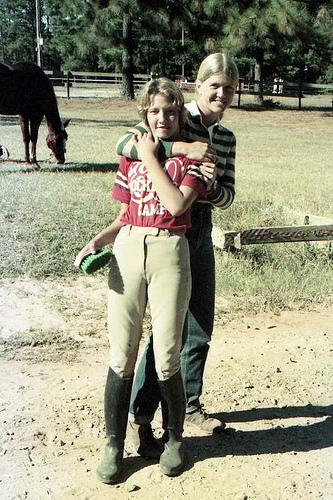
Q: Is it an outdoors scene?
A: Yes, it is outdoors.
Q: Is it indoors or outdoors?
A: It is outdoors.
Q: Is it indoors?
A: No, it is outdoors.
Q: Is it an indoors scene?
A: No, it is outdoors.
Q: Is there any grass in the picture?
A: Yes, there is grass.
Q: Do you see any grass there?
A: Yes, there is grass.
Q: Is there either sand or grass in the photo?
A: Yes, there is grass.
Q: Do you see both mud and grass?
A: No, there is grass but no mud.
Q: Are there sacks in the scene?
A: No, there are no sacks.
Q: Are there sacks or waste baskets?
A: No, there are no sacks or waste baskets.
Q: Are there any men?
A: No, there are no men.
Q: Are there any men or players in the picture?
A: No, there are no men or players.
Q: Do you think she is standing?
A: Yes, the girl is standing.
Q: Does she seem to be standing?
A: Yes, the girl is standing.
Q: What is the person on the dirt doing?
A: The girl is standing.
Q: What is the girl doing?
A: The girl is standing.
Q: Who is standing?
A: The girl is standing.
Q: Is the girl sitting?
A: No, the girl is standing.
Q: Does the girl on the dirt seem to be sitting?
A: No, the girl is standing.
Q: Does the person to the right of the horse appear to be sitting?
A: No, the girl is standing.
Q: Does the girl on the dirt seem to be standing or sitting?
A: The girl is standing.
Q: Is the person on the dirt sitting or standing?
A: The girl is standing.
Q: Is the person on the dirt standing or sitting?
A: The girl is standing.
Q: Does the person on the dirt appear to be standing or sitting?
A: The girl is standing.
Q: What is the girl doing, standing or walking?
A: The girl is standing.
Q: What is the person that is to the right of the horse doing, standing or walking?
A: The girl is standing.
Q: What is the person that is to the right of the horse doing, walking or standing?
A: The girl is standing.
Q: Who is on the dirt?
A: The girl is on the dirt.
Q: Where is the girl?
A: The girl is on the dirt.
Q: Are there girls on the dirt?
A: Yes, there is a girl on the dirt.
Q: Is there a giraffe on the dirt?
A: No, there is a girl on the dirt.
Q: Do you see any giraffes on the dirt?
A: No, there is a girl on the dirt.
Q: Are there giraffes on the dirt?
A: No, there is a girl on the dirt.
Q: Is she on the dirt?
A: Yes, the girl is on the dirt.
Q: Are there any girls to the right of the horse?
A: Yes, there is a girl to the right of the horse.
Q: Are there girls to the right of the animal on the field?
A: Yes, there is a girl to the right of the horse.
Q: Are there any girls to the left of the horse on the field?
A: No, the girl is to the right of the horse.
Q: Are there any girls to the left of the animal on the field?
A: No, the girl is to the right of the horse.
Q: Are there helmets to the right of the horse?
A: No, there is a girl to the right of the horse.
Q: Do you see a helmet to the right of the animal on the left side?
A: No, there is a girl to the right of the horse.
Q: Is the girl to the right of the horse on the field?
A: Yes, the girl is to the right of the horse.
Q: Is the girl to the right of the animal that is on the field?
A: Yes, the girl is to the right of the horse.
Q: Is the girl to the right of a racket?
A: No, the girl is to the right of the horse.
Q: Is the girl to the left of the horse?
A: No, the girl is to the right of the horse.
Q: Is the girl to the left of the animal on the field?
A: No, the girl is to the right of the horse.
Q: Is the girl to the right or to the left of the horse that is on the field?
A: The girl is to the right of the horse.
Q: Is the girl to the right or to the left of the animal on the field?
A: The girl is to the right of the horse.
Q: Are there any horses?
A: Yes, there is a horse.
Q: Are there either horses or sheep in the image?
A: Yes, there is a horse.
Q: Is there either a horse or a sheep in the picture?
A: Yes, there is a horse.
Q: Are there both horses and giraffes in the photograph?
A: No, there is a horse but no giraffes.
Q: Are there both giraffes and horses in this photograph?
A: No, there is a horse but no giraffes.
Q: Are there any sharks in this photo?
A: No, there are no sharks.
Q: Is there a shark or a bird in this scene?
A: No, there are no sharks or birds.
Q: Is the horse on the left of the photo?
A: Yes, the horse is on the left of the image.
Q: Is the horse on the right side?
A: No, the horse is on the left of the image.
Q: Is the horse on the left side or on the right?
A: The horse is on the left of the image.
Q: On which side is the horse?
A: The horse is on the left of the image.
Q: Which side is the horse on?
A: The horse is on the left of the image.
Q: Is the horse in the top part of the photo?
A: Yes, the horse is in the top of the image.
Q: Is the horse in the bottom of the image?
A: No, the horse is in the top of the image.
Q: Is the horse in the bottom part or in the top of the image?
A: The horse is in the top of the image.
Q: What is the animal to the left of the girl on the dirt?
A: The animal is a horse.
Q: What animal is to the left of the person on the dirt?
A: The animal is a horse.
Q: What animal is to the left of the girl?
A: The animal is a horse.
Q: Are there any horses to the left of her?
A: Yes, there is a horse to the left of the girl.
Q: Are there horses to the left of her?
A: Yes, there is a horse to the left of the girl.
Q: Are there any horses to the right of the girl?
A: No, the horse is to the left of the girl.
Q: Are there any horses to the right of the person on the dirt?
A: No, the horse is to the left of the girl.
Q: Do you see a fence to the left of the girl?
A: No, there is a horse to the left of the girl.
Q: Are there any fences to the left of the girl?
A: No, there is a horse to the left of the girl.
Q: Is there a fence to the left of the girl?
A: No, there is a horse to the left of the girl.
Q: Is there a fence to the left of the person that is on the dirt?
A: No, there is a horse to the left of the girl.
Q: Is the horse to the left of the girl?
A: Yes, the horse is to the left of the girl.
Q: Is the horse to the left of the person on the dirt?
A: Yes, the horse is to the left of the girl.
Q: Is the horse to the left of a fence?
A: No, the horse is to the left of the girl.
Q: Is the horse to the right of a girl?
A: No, the horse is to the left of a girl.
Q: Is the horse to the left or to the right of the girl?
A: The horse is to the left of the girl.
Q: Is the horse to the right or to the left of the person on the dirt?
A: The horse is to the left of the girl.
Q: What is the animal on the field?
A: The animal is a horse.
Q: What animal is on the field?
A: The animal is a horse.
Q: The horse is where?
A: The horse is on the field.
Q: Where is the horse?
A: The horse is on the field.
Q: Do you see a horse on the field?
A: Yes, there is a horse on the field.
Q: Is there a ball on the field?
A: No, there is a horse on the field.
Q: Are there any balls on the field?
A: No, there is a horse on the field.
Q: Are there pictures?
A: No, there are no pictures.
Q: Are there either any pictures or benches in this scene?
A: No, there are no pictures or benches.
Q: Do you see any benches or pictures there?
A: No, there are no pictures or benches.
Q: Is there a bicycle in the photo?
A: No, there are no bicycles.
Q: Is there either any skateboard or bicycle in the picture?
A: No, there are no bicycles or skateboards.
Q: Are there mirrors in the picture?
A: No, there are no mirrors.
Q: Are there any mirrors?
A: No, there are no mirrors.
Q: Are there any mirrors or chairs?
A: No, there are no mirrors or chairs.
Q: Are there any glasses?
A: No, there are no glasses.